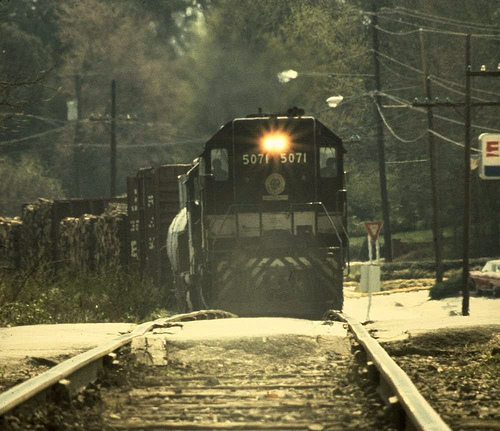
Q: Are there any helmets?
A: No, there are no helmets.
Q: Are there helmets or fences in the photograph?
A: No, there are no helmets or fences.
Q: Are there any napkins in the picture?
A: No, there are no napkins.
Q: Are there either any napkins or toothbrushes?
A: No, there are no napkins or toothbrushes.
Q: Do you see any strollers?
A: No, there are no strollers.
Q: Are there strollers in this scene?
A: No, there are no strollers.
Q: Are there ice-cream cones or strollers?
A: No, there are no strollers or ice-cream cones.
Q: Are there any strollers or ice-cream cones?
A: No, there are no strollers or ice-cream cones.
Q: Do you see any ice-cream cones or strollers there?
A: No, there are no strollers or ice-cream cones.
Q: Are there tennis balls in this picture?
A: No, there are no tennis balls.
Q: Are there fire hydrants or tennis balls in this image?
A: No, there are no tennis balls or fire hydrants.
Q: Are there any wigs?
A: No, there are no wigs.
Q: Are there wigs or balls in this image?
A: No, there are no wigs or balls.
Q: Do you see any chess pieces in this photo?
A: No, there are no chess pieces.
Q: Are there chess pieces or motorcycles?
A: No, there are no chess pieces or motorcycles.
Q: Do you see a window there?
A: Yes, there is a window.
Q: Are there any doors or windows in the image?
A: Yes, there is a window.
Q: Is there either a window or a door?
A: Yes, there is a window.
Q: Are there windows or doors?
A: Yes, there is a window.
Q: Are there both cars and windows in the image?
A: Yes, there are both a window and a car.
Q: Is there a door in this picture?
A: No, there are no doors.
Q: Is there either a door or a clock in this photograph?
A: No, there are no doors or clocks.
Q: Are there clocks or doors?
A: No, there are no doors or clocks.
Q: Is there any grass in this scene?
A: Yes, there is grass.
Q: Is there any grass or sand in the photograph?
A: Yes, there is grass.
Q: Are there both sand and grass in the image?
A: No, there is grass but no sand.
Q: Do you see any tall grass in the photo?
A: Yes, there is tall grass.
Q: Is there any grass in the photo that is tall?
A: Yes, there is grass that is tall.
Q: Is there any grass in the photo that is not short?
A: Yes, there is tall grass.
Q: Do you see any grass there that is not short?
A: Yes, there is tall grass.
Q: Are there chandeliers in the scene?
A: No, there are no chandeliers.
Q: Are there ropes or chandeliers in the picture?
A: No, there are no chandeliers or ropes.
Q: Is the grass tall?
A: Yes, the grass is tall.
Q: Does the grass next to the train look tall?
A: Yes, the grass is tall.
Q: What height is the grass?
A: The grass is tall.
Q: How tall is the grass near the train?
A: The grass is tall.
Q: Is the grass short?
A: No, the grass is tall.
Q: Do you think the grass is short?
A: No, the grass is tall.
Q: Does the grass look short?
A: No, the grass is tall.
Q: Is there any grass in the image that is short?
A: No, there is grass but it is tall.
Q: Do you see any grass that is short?
A: No, there is grass but it is tall.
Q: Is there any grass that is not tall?
A: No, there is grass but it is tall.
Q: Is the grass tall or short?
A: The grass is tall.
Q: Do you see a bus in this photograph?
A: No, there are no buses.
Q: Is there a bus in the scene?
A: No, there are no buses.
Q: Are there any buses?
A: No, there are no buses.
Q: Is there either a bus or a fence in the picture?
A: No, there are no buses or fences.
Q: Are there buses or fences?
A: No, there are no buses or fences.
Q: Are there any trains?
A: Yes, there is a train.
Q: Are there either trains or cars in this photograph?
A: Yes, there is a train.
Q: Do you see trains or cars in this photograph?
A: Yes, there is a train.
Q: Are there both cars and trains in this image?
A: Yes, there are both a train and cars.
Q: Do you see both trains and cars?
A: Yes, there are both a train and cars.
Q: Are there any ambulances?
A: No, there are no ambulances.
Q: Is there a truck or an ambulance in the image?
A: No, there are no ambulances or trucks.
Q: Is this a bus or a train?
A: This is a train.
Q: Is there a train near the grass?
A: Yes, there is a train near the grass.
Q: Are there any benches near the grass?
A: No, there is a train near the grass.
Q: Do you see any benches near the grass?
A: No, there is a train near the grass.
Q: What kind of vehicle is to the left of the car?
A: The vehicle is a train.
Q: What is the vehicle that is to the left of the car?
A: The vehicle is a train.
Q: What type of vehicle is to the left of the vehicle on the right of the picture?
A: The vehicle is a train.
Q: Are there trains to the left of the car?
A: Yes, there is a train to the left of the car.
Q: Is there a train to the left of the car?
A: Yes, there is a train to the left of the car.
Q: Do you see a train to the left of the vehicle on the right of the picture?
A: Yes, there is a train to the left of the car.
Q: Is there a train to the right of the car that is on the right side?
A: No, the train is to the left of the car.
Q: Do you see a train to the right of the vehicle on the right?
A: No, the train is to the left of the car.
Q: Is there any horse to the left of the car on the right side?
A: No, there is a train to the left of the car.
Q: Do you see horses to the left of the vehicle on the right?
A: No, there is a train to the left of the car.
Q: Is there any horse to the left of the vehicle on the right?
A: No, there is a train to the left of the car.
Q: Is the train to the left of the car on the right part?
A: Yes, the train is to the left of the car.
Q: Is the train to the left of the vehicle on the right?
A: Yes, the train is to the left of the car.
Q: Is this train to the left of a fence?
A: No, the train is to the left of the car.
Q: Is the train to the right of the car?
A: No, the train is to the left of the car.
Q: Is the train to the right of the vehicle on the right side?
A: No, the train is to the left of the car.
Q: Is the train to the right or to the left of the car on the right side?
A: The train is to the left of the car.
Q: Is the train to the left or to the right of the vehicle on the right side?
A: The train is to the left of the car.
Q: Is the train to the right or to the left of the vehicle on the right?
A: The train is to the left of the car.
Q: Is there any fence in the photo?
A: No, there are no fences.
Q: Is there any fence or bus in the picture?
A: No, there are no fences or buses.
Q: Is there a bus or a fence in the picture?
A: No, there are no fences or buses.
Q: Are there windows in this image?
A: Yes, there is a window.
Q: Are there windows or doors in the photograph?
A: Yes, there is a window.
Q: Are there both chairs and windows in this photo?
A: No, there is a window but no chairs.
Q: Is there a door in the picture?
A: No, there are no doors.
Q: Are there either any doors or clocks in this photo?
A: No, there are no doors or clocks.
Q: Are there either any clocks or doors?
A: No, there are no doors or clocks.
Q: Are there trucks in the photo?
A: No, there are no trucks.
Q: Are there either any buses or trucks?
A: No, there are no trucks or buses.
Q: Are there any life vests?
A: No, there are no life vests.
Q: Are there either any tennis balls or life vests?
A: No, there are no life vests or tennis balls.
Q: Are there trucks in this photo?
A: No, there are no trucks.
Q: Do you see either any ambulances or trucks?
A: No, there are no trucks or ambulances.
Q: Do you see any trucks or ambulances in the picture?
A: No, there are no trucks or ambulances.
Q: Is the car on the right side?
A: Yes, the car is on the right of the image.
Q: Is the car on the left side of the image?
A: No, the car is on the right of the image.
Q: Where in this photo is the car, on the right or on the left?
A: The car is on the right of the image.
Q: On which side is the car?
A: The car is on the right of the image.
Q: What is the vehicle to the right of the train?
A: The vehicle is a car.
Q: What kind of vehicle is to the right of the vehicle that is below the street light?
A: The vehicle is a car.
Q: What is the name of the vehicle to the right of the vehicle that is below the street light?
A: The vehicle is a car.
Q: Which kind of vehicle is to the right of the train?
A: The vehicle is a car.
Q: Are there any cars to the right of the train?
A: Yes, there is a car to the right of the train.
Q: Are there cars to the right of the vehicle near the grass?
A: Yes, there is a car to the right of the train.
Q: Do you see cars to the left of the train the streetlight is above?
A: No, the car is to the right of the train.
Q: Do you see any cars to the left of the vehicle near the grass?
A: No, the car is to the right of the train.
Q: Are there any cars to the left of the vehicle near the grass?
A: No, the car is to the right of the train.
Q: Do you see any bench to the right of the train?
A: No, there is a car to the right of the train.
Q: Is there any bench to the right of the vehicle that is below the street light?
A: No, there is a car to the right of the train.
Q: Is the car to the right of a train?
A: Yes, the car is to the right of a train.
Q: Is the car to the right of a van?
A: No, the car is to the right of a train.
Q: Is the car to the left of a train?
A: No, the car is to the right of a train.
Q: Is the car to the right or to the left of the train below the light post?
A: The car is to the right of the train.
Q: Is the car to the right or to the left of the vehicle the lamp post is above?
A: The car is to the right of the train.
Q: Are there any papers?
A: No, there are no papers.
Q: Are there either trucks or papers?
A: No, there are no papers or trucks.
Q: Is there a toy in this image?
A: No, there are no toys.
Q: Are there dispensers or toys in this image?
A: No, there are no toys or dispensers.